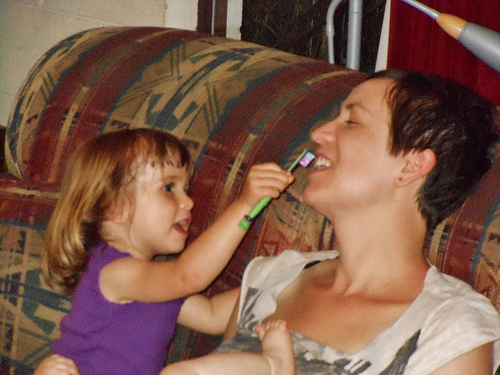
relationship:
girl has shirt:
[58, 138, 179, 372] [83, 287, 108, 336]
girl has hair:
[58, 138, 179, 372] [78, 139, 106, 166]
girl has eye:
[58, 138, 179, 372] [166, 187, 172, 192]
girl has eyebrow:
[58, 138, 179, 372] [163, 175, 180, 182]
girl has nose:
[58, 138, 179, 372] [183, 196, 191, 208]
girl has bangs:
[58, 138, 179, 372] [153, 133, 182, 164]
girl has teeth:
[58, 138, 179, 372] [183, 223, 186, 225]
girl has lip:
[58, 138, 179, 372] [183, 232, 187, 239]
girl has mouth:
[58, 138, 179, 372] [174, 217, 193, 240]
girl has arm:
[58, 138, 179, 372] [125, 266, 195, 283]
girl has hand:
[58, 138, 179, 372] [248, 170, 277, 193]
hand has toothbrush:
[248, 170, 277, 193] [301, 154, 308, 164]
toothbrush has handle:
[301, 154, 308, 164] [258, 202, 265, 210]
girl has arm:
[58, 138, 179, 372] [198, 304, 224, 321]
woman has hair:
[293, 61, 499, 374] [412, 85, 463, 126]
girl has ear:
[58, 138, 179, 372] [107, 198, 125, 221]